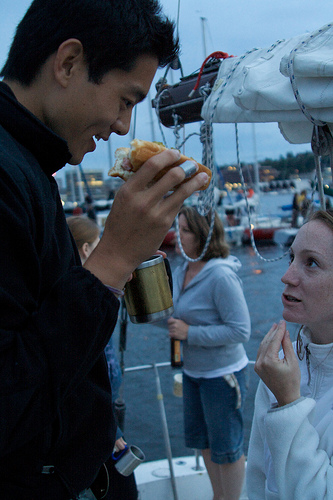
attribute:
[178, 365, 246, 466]
jeans — short, denim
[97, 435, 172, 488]
mug — blue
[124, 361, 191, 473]
railing — white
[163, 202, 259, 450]
lady — young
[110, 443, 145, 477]
mug — silver, blue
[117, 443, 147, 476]
cup — silver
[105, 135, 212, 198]
hot dog — half-eaten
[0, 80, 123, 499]
jacket — fall 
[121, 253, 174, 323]
mug — silver, gold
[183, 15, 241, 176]
pole — silver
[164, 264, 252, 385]
jacket — gray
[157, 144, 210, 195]
ring — metal 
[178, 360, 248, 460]
jeans — blue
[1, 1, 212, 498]
man — young, adult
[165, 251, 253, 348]
coat — gray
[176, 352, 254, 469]
jeans — blue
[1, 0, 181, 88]
hair — black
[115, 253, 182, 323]
cup — gold, silver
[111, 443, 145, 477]
cup — blue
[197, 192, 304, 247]
boats — blue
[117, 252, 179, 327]
mug — gold, silver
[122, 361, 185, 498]
rail — metal